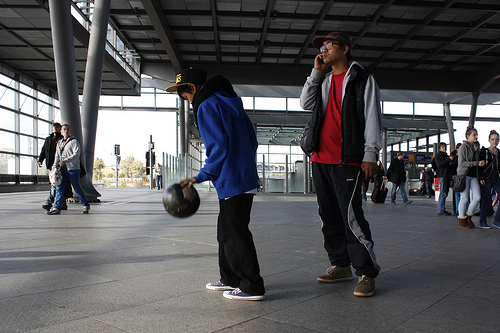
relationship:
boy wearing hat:
[161, 65, 266, 301] [165, 60, 201, 95]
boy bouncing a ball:
[163, 46, 283, 321] [157, 168, 203, 220]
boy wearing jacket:
[162, 61, 269, 301] [118, 57, 306, 319]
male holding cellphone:
[299, 31, 382, 296] [304, 53, 322, 69]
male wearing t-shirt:
[299, 31, 382, 296] [308, 65, 358, 165]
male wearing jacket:
[299, 31, 382, 296] [189, 92, 260, 198]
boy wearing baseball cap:
[161, 65, 266, 301] [165, 66, 206, 92]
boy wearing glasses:
[297, 31, 385, 296] [318, 37, 345, 54]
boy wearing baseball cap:
[162, 61, 269, 301] [163, 65, 202, 92]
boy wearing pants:
[129, 50, 288, 314] [185, 127, 287, 327]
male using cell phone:
[299, 31, 382, 296] [313, 50, 338, 65]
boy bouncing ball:
[161, 65, 266, 301] [160, 179, 204, 219]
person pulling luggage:
[384, 153, 416, 205] [367, 178, 391, 209]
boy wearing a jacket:
[161, 65, 266, 301] [187, 95, 262, 192]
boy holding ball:
[136, 47, 318, 322] [157, 182, 204, 222]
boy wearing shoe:
[162, 61, 269, 301] [205, 280, 239, 290]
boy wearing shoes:
[162, 61, 269, 301] [222, 286, 265, 301]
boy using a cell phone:
[161, 65, 266, 301] [320, 56, 328, 65]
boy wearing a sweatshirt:
[297, 31, 385, 296] [300, 62, 382, 163]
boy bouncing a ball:
[161, 65, 266, 301] [155, 176, 203, 220]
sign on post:
[114, 143, 120, 155] [116, 155, 118, 187]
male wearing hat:
[292, 20, 406, 303] [302, 23, 357, 53]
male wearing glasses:
[292, 20, 406, 303] [306, 42, 335, 55]